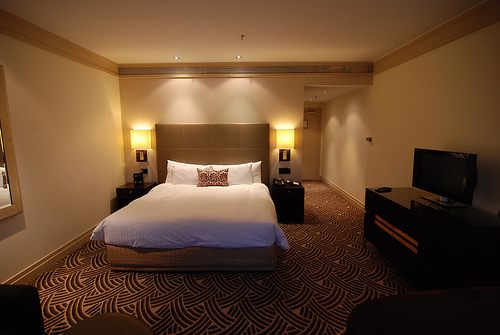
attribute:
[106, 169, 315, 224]
nightstands — wooden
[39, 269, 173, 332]
carpet — black, yellow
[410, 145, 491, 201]
screen tv — black,  flat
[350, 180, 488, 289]
dresser —  black,  gold, shiny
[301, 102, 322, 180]
door — entry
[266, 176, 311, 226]
night stand — small, black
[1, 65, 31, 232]
framed mirror — yellow